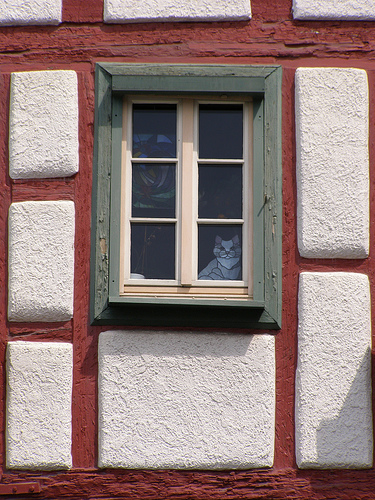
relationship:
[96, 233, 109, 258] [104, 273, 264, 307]
paint on window trim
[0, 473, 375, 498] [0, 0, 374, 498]
grooves on wall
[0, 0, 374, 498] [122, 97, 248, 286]
trim on window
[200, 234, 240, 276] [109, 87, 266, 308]
cat in paned window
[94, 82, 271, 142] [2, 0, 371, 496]
shadow on building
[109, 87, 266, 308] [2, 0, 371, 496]
paned window on building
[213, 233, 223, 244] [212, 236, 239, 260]
ear on head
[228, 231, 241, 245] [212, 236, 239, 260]
ear on head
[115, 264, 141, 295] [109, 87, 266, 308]
corner on paned window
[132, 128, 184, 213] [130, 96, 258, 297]
art in window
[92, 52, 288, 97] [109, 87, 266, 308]
frame on paned window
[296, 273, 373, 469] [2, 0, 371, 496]
block on building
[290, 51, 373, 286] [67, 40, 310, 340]
block left of window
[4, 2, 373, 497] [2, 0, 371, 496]
trim of building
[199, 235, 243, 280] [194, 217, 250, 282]
cat in window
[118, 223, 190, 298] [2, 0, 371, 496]
potted plant inside building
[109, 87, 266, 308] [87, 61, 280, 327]
paned window has frame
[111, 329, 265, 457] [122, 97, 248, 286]
stucco beneath window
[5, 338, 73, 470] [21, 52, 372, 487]
rectangle on side of wall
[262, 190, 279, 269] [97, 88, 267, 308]
paint chipping on spots of frame